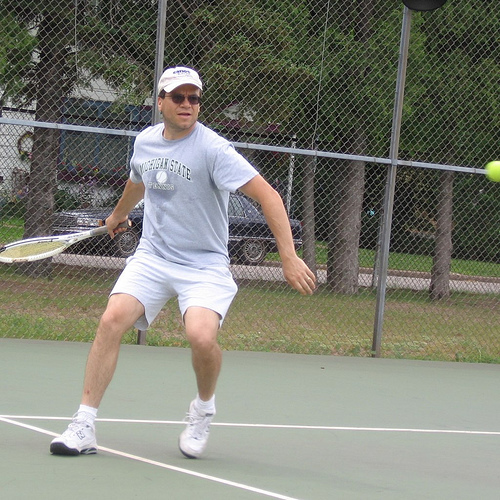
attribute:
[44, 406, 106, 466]
shoes — white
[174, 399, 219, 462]
shoes — white, black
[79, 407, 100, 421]
socks — white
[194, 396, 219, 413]
socks — white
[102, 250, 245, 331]
shorts — white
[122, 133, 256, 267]
shirt — gray, grey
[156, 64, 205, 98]
hat — white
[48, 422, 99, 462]
tennis shoe — black, white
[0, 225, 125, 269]
tennis racket — white, grey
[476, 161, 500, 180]
tennis ball — yellow, green, round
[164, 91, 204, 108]
eye-glasses — dark, black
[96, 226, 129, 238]
handle — gray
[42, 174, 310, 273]
car — navy blue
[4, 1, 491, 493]
tennis court — green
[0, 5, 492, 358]
fence — metal